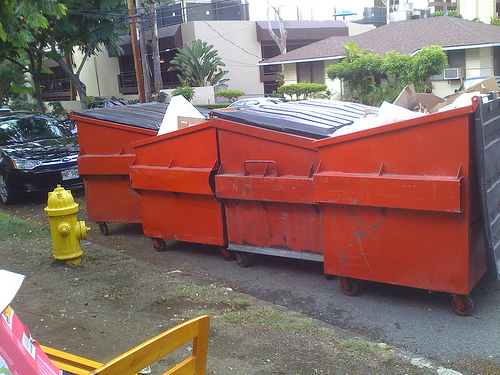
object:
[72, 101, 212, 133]
fire lid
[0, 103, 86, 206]
car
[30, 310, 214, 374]
chair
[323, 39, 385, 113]
tree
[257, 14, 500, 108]
house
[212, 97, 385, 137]
lid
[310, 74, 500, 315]
trash can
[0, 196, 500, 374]
paved street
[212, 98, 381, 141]
cover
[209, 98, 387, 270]
bin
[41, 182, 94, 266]
hydrant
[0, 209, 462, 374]
curb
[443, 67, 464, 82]
ac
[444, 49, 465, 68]
window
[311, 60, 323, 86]
window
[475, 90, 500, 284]
lid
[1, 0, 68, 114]
tree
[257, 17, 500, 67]
roof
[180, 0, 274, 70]
telephone lines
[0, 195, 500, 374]
ground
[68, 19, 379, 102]
building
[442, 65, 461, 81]
air conditioner